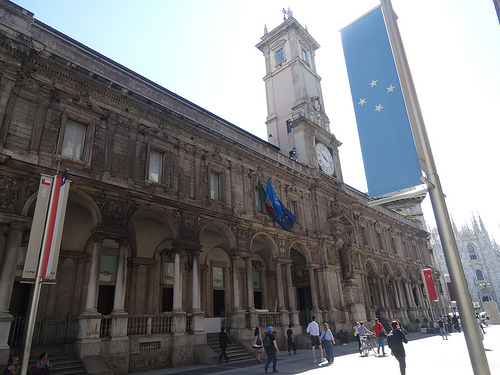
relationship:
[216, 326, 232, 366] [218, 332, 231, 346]
person wearing black shirt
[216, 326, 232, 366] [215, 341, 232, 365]
person wearing black pants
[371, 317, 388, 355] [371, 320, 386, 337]
person wearing red shirt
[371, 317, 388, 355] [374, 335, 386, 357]
person wearing blue jeans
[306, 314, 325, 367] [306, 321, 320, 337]
person wearing white shirt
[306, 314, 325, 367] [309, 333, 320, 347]
person wearing dark shorts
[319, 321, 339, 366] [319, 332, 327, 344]
person holding bag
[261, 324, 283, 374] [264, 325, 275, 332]
person wearing blue hat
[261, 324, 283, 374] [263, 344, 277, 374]
person wearing dark pants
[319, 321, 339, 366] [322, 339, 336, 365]
person wearing blue pants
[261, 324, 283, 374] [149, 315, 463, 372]
person on sidewalk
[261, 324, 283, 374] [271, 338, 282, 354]
person has right arm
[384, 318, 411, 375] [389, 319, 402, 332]
people has head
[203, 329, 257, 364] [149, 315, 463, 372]
steps beside sidewalk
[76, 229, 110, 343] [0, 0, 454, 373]
pillar on building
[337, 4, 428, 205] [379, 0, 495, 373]
banner on pole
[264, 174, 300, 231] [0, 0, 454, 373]
flags on building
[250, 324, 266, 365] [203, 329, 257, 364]
person beside steps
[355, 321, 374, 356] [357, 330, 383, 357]
person walking a bicycle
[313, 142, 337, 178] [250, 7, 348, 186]
clock face on clock tower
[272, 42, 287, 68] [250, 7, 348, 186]
window on clock tower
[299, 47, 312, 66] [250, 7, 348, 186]
window on clock tower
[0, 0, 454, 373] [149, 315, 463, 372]
building beside sidewalk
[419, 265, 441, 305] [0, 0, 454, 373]
banner on building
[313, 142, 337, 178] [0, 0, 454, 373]
clock face on front of building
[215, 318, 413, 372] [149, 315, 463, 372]
people walking on sidewalk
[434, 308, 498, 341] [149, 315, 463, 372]
people walking on sidewalk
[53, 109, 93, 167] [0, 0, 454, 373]
window on building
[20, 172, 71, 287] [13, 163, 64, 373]
banner on pole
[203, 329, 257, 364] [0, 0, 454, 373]
steps lead to building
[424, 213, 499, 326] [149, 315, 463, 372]
cathedral beyond sidewalk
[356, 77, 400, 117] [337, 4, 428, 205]
stars on banner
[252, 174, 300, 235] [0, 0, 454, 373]
flags on building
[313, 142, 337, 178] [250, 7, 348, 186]
clock face on bottom of clock tower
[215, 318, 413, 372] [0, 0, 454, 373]
people walking beside building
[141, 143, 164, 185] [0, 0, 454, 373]
window on building